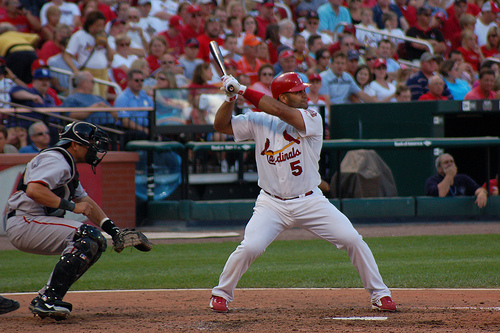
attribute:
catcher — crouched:
[0, 114, 153, 326]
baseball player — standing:
[190, 41, 403, 322]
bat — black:
[204, 31, 238, 104]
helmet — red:
[262, 70, 316, 104]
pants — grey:
[0, 202, 95, 262]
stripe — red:
[16, 215, 88, 236]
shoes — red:
[22, 284, 85, 324]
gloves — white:
[215, 72, 252, 104]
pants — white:
[210, 174, 398, 305]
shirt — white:
[231, 105, 334, 201]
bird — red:
[259, 134, 275, 160]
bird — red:
[277, 126, 304, 153]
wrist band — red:
[239, 81, 274, 109]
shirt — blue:
[116, 88, 158, 126]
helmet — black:
[55, 119, 102, 145]